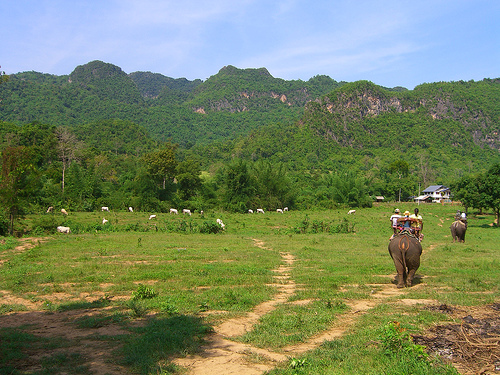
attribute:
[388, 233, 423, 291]
elephant — moving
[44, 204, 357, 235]
herd — small, white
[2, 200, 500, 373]
grass — grassy, green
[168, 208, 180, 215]
animal — gray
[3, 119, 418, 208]
trees — tall, leafy, green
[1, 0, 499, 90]
sky — cloudy, clear, blue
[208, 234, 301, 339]
path — dirt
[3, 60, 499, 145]
mountain — tall, rocky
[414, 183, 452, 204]
house — white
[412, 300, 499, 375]
pool — muddy, brown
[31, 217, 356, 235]
shrubs — green